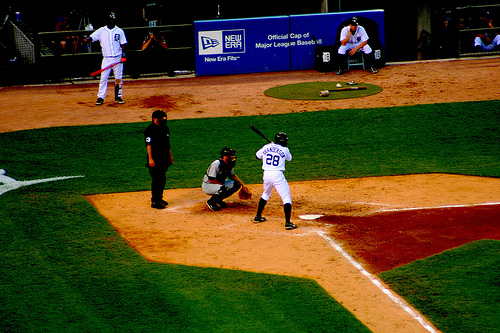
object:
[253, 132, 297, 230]
player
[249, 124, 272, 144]
bat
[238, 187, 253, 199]
mitt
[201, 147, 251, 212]
catcher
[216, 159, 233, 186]
gear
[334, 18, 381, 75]
person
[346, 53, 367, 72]
chair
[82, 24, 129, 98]
uniform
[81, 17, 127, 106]
player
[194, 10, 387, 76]
advertisement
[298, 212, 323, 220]
plate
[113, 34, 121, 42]
logo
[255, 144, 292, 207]
uniform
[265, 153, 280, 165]
number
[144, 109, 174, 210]
umpire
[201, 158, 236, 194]
uniform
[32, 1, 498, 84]
dugout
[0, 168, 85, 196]
symbol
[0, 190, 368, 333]
grass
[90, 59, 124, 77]
bat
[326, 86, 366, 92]
bat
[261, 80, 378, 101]
deck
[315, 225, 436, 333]
chalk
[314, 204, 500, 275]
dirt